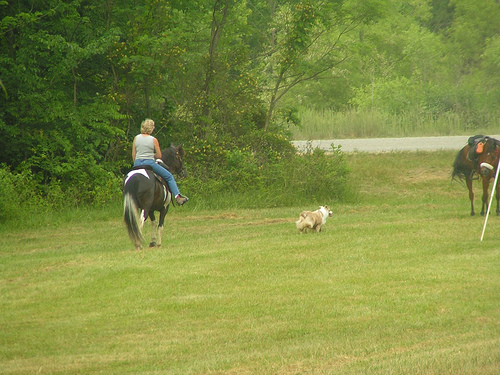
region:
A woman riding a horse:
[122, 111, 194, 199]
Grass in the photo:
[156, 307, 339, 359]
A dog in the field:
[292, 194, 348, 235]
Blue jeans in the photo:
[129, 157, 179, 207]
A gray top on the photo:
[133, 129, 158, 165]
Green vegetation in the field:
[208, 129, 260, 178]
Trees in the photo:
[93, 9, 243, 89]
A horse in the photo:
[114, 142, 195, 237]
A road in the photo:
[344, 129, 387, 154]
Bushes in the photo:
[173, 0, 433, 75]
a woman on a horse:
[118, 116, 187, 259]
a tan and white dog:
[298, 203, 333, 233]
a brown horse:
[463, 130, 497, 220]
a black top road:
[321, 132, 458, 156]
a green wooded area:
[8, 15, 115, 209]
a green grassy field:
[172, 269, 426, 357]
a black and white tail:
[122, 191, 144, 251]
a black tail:
[452, 146, 472, 176]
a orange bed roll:
[467, 141, 482, 159]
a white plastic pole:
[479, 175, 497, 249]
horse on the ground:
[79, 94, 223, 251]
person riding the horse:
[112, 105, 179, 186]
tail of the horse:
[100, 177, 151, 274]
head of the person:
[130, 110, 160, 145]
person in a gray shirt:
[121, 106, 171, 163]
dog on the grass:
[281, 185, 348, 255]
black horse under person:
[98, 145, 199, 240]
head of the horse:
[168, 139, 189, 177]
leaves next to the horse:
[38, 133, 100, 193]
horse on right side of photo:
[431, 127, 497, 195]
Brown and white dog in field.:
[297, 198, 334, 235]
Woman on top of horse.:
[126, 117, 185, 204]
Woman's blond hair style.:
[139, 118, 156, 134]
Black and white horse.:
[126, 147, 186, 250]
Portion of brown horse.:
[450, 137, 498, 214]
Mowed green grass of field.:
[192, 263, 460, 362]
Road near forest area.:
[333, 133, 465, 150]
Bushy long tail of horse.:
[122, 188, 145, 251]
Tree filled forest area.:
[0, 2, 348, 209]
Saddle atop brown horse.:
[466, 129, 496, 157]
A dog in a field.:
[273, 203, 369, 247]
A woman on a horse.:
[118, 118, 203, 242]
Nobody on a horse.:
[437, 130, 497, 205]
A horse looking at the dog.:
[263, 130, 498, 240]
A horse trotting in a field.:
[104, 120, 213, 282]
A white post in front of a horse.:
[466, 158, 499, 246]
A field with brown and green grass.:
[168, 234, 432, 296]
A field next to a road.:
[358, 124, 450, 304]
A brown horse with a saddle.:
[455, 136, 495, 199]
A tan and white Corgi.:
[268, 196, 363, 236]